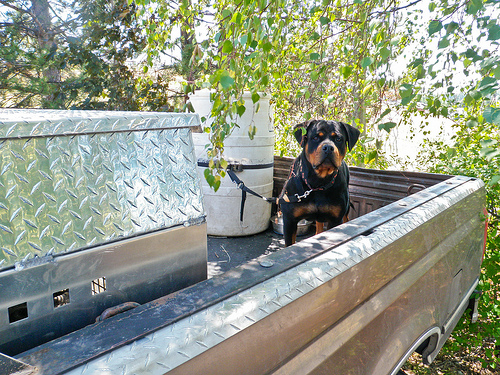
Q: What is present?
A: A dog.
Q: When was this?
A: Daytime.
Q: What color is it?
A: Black.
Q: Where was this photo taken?
A: In the back of a pickup truck.